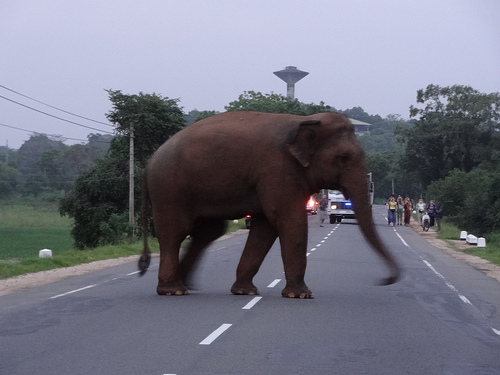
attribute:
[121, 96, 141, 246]
pole — tall, silver, metal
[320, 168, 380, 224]
truck — white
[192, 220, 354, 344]
lines — white, dotted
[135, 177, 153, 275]
tail — brown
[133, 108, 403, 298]
elephant — brown, large, adult, grey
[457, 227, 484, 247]
objects — white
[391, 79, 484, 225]
trees — green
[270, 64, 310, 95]
tower — gray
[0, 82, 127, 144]
wires — black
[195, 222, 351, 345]
stripes — white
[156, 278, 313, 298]
feet — flat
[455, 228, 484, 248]
blocks — white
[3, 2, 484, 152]
sky — gray, overcast, cloudy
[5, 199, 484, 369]
street — paved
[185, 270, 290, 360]
lines — white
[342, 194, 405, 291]
trunk — curved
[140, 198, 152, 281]
tail — long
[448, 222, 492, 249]
posts — white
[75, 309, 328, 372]
pavement — gray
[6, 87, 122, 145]
lines — power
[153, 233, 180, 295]
leg — back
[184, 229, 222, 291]
leg — back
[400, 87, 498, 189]
tree — green leafed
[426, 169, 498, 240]
tree — green leafed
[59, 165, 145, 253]
tree — green leafed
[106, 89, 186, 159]
tree — green leafed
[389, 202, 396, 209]
shirt — yellow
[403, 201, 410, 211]
shirt — red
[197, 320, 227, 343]
line — white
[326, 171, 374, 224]
van — white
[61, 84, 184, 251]
tree — tall, green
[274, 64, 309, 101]
building — metal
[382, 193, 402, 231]
person — walking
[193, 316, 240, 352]
line — white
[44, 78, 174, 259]
trees — green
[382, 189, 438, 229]
people — walking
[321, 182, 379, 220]
vehicle — white